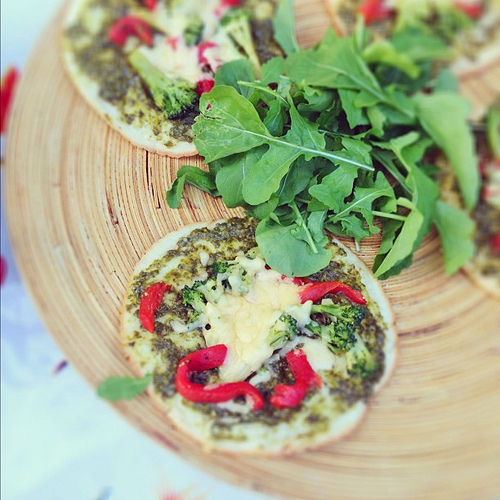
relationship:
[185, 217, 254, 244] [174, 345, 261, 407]
seasoning on pepper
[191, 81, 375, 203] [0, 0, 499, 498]
leaves on dish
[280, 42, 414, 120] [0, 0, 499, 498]
green lettuce on dish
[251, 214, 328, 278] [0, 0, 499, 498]
leaves on dish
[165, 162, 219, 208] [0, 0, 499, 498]
leaves on dish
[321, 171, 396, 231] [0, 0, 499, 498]
leaves on dish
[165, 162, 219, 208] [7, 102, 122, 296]
leaves on plate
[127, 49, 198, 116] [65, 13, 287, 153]
broccoli on food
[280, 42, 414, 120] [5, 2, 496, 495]
green lettuce at center of dish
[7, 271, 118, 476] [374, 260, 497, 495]
table under plate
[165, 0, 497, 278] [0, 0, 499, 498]
green lettuce on surface of dish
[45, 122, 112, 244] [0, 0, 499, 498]
line on dish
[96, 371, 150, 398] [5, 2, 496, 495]
leaf on dish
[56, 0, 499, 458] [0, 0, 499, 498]
food served on dish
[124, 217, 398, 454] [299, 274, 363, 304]
bread with pepper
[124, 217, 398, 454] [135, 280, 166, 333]
bread with food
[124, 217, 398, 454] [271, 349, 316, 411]
bread with pepper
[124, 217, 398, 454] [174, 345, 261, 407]
bread with pepper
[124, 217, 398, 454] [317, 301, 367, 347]
bread with broccoli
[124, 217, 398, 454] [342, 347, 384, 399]
bread with broccoli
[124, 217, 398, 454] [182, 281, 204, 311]
bread with broccoli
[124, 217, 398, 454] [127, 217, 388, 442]
bread with seasoning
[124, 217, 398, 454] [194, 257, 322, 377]
bread with cheese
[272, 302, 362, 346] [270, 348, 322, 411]
broccoli on top of pepper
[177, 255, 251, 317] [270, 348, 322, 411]
broccoli on top of pepper